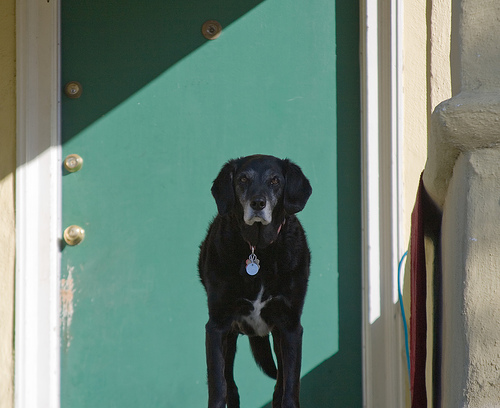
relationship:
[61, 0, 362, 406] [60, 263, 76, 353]
door has scratch marks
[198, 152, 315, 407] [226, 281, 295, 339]
dog has white stripes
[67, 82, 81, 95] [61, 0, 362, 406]
deadbolt on door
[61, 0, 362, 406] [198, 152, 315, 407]
door behind dog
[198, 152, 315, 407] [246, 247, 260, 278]
dog has dog tag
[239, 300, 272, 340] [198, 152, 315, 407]
underbelly on dog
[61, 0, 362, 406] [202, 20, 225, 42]
door has peephole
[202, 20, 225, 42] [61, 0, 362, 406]
peephole on door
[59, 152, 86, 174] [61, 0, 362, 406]
deadbolt on door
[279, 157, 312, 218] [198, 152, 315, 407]
ear of dog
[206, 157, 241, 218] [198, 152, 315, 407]
ear of dog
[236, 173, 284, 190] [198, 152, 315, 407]
eyes of dog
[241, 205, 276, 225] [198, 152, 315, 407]
mouth of dog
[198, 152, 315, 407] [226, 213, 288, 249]
dog wearing collar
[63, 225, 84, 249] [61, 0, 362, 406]
door knob on door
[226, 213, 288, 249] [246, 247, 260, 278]
collar has dog tag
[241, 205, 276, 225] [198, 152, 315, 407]
mouth on dog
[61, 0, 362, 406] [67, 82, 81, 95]
door has deadbolt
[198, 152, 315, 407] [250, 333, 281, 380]
dog has tail